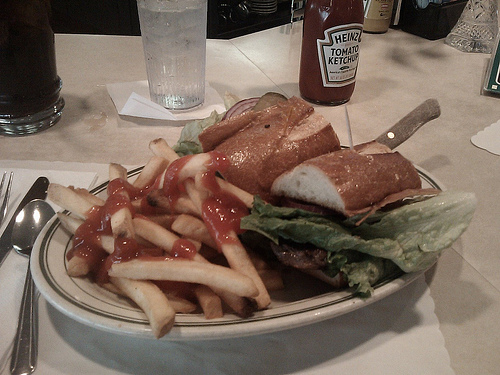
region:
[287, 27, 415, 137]
Bottle of ketchup on table.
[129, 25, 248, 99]
Glass of water near ketchup.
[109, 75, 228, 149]
White beverage napkin under glass.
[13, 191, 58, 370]
Silver spoon near side of plate.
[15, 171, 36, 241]
Silver knife next to spoon.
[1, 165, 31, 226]
Silver fork next to knife.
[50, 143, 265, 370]
White place mat underneath plate.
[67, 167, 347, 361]
White round plate with food on it.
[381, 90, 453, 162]
Wood handle on steak knife.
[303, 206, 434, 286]
Green lettuce hanging off of sandwich.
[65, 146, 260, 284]
fries on a plate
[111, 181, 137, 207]
ketchup on french fries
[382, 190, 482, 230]
lettuce on a sandwich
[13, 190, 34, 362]
spoon next to a plate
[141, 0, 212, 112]
tall glass of water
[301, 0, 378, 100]
ketchup on a table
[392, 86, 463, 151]
knife on a fork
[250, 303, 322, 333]
plate on a table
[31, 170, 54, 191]
knife next to a spoon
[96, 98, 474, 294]
food on a plate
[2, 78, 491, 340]
french fries on a plate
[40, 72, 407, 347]
frenches in a pile on the plate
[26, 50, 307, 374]
french fries with ketchup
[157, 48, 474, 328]
a sandwich on a plate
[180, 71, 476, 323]
a sanwich cut in half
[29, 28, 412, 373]
a sandwich cut in half on a plate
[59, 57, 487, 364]
sandwich and french fries on a plate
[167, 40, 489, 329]
lettuces on a sandwich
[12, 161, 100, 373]
spoons on a table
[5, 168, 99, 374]
silver spoons on a table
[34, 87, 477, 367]
A plate of food.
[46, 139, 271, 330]
French fries with ketchup on top.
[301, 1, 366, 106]
A red bottle of ketchup.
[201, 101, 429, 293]
A sandwich.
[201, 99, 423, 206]
A golden brown bread top of a sub.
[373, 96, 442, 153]
A wooden knife handle.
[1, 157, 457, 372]
A white placemat.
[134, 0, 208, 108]
A tall clear glass.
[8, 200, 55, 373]
A silver spoon.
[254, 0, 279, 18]
A stack of plates.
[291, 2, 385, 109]
A bottle of Heinz ketchup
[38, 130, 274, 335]
French fries with ketchup on them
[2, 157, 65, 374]
A fork, knife and spoon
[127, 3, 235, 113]
A glass of ice water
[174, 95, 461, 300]
A sandwich with french bread and lettuce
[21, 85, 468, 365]
A plate with a sandwich and fries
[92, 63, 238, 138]
A white napkin under a glass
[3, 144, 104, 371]
A white napkin under silverware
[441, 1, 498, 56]
Part of a salt shaker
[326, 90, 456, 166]
A wooden handled knife on a plate